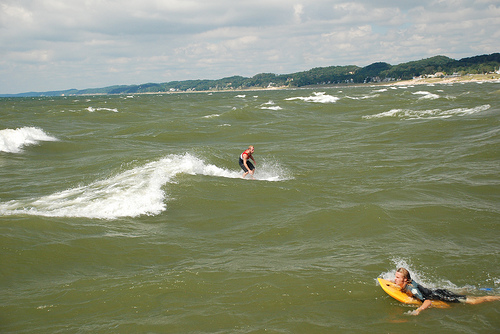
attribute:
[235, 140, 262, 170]
man — surfing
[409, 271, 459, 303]
wetsuit — black, gray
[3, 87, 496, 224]
waves — Small, white, capped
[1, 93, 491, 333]
water — green, grey and green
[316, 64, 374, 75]
hill — tree-covered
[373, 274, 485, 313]
surfboard — yellow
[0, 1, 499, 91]
sky — cloudy, blue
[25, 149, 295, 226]
wave — white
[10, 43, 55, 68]
cloud — gray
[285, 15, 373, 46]
cloud — gray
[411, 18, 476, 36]
cloud — gray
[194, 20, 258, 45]
cloud — gray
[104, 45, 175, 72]
cloud — gray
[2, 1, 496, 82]
sky — heavy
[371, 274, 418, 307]
board — yellow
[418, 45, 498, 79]
hillside — treed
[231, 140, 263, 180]
man — standing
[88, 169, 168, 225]
waves — white, capped